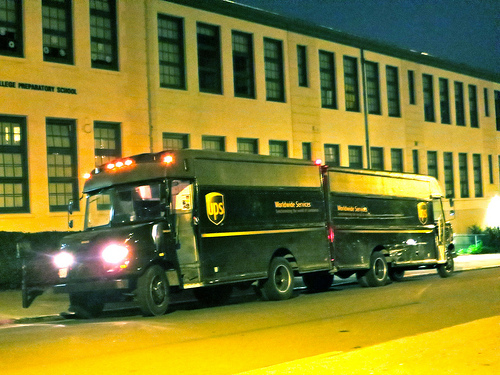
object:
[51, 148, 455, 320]
truck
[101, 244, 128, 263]
lights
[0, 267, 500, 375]
road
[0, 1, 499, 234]
building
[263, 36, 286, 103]
window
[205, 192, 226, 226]
logo